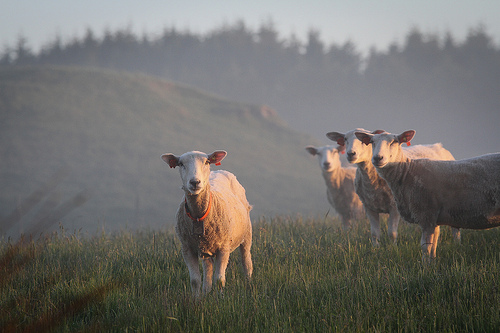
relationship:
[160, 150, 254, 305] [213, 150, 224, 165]
goat with tag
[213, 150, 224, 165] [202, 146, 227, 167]
tag in ear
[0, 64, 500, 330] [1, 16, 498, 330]
grass in field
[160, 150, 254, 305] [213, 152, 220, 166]
goat with tag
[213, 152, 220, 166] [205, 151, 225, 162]
tag attached to ear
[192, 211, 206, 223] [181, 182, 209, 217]
bell on neck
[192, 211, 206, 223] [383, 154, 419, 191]
bell on neck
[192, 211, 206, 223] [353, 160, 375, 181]
bell on neck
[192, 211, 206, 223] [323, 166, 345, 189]
bell on neck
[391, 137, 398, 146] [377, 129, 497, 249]
eyes of sheep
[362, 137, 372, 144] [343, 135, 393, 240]
eyes of sheep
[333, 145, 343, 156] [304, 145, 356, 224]
eyes of sheep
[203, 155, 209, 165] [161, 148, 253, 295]
eyes of sheep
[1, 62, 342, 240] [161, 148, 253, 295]
hill behind sheep